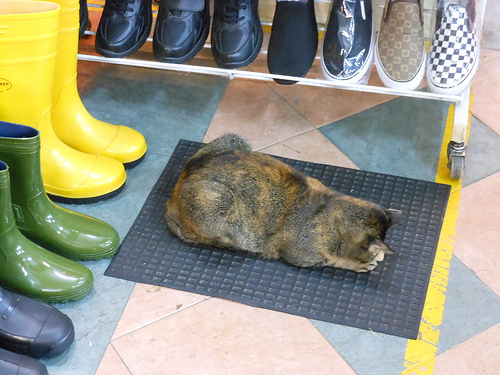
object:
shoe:
[311, 1, 371, 85]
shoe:
[210, 0, 257, 68]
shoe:
[99, 0, 130, 55]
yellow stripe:
[395, 87, 477, 367]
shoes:
[222, 8, 476, 99]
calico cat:
[168, 131, 403, 279]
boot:
[0, 3, 130, 203]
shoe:
[93, 2, 147, 57]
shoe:
[208, 1, 263, 68]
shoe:
[267, 0, 317, 84]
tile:
[347, 108, 406, 154]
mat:
[359, 207, 447, 330]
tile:
[225, 81, 337, 165]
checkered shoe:
[430, 4, 476, 90]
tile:
[467, 45, 499, 135]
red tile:
[453, 184, 497, 278]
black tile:
[318, 85, 497, 185]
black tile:
[307, 247, 498, 374]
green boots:
[0, 121, 118, 262]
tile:
[123, 284, 214, 325]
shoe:
[376, 2, 428, 96]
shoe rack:
[76, 0, 486, 108]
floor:
[38, 1, 478, 375]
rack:
[61, 0, 483, 187]